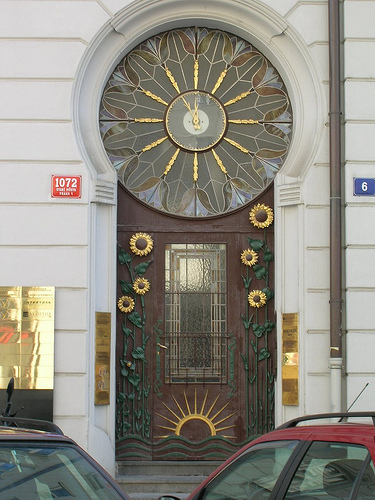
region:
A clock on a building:
[57, 30, 344, 195]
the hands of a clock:
[174, 85, 218, 147]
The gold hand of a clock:
[168, 78, 217, 154]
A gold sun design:
[135, 385, 245, 455]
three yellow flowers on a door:
[119, 226, 154, 334]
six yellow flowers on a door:
[120, 197, 274, 336]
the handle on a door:
[144, 325, 185, 372]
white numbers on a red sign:
[38, 167, 100, 211]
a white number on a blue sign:
[348, 172, 370, 216]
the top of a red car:
[218, 413, 365, 495]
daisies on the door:
[100, 229, 166, 371]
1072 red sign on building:
[46, 165, 94, 208]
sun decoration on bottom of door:
[149, 389, 250, 451]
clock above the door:
[110, 4, 343, 245]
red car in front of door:
[199, 416, 373, 467]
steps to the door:
[118, 445, 243, 498]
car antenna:
[334, 380, 373, 430]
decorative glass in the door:
[156, 232, 249, 406]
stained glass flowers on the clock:
[130, 16, 303, 225]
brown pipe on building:
[317, 42, 365, 361]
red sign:
[50, 175, 80, 197]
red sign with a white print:
[49, 174, 81, 198]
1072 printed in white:
[50, 177, 80, 188]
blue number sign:
[353, 176, 373, 193]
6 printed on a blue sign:
[353, 176, 373, 193]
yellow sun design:
[154, 386, 237, 442]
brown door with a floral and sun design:
[118, 181, 276, 464]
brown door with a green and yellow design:
[117, 190, 272, 464]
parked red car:
[184, 408, 374, 496]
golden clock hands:
[182, 95, 206, 129]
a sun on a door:
[160, 382, 247, 447]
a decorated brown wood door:
[111, 222, 274, 460]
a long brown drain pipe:
[318, 4, 359, 357]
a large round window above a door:
[89, 9, 303, 204]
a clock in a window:
[163, 84, 230, 153]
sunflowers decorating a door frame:
[242, 195, 272, 312]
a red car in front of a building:
[183, 416, 374, 493]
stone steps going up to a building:
[108, 460, 261, 498]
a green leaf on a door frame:
[114, 241, 132, 268]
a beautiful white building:
[2, 3, 371, 480]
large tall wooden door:
[102, 171, 289, 487]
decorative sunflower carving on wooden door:
[113, 227, 156, 467]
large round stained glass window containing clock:
[95, 32, 310, 224]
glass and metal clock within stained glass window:
[161, 86, 230, 158]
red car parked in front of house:
[128, 381, 373, 498]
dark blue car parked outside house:
[0, 407, 153, 499]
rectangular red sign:
[43, 169, 90, 205]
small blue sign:
[350, 173, 373, 194]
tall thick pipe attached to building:
[322, 0, 353, 498]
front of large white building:
[2, 0, 371, 495]